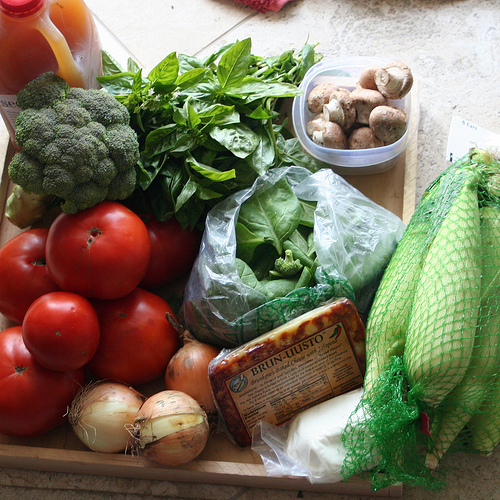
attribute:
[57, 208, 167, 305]
tomato — large, round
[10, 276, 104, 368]
tomato — round, large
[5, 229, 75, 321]
tomato — large, round